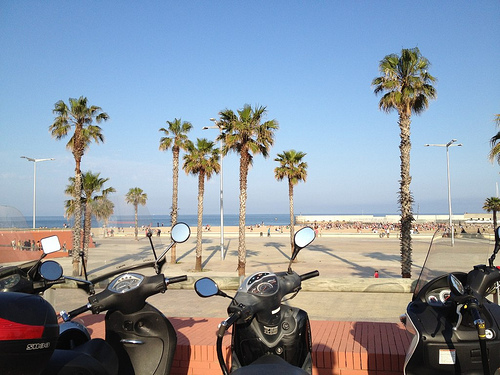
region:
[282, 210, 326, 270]
Mirror attached to handle bars.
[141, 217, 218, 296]
Mirror attached to handle bars.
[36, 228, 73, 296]
Mirrors attached to handle bars.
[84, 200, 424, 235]
Many people on the bach.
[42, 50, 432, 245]
a group of palm trees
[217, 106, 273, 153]
the fronds of a palm tree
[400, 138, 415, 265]
the trunk of a palm tree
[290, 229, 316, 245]
a side view mirror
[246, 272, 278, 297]
gauges on a scooter dash board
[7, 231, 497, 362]
a row of motorscooters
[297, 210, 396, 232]
people on a beach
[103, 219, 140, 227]
a volleyball net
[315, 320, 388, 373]
a red brick wall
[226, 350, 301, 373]
a black leather seat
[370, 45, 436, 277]
A palm tree on the beach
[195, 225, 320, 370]
A scooter parked by the beach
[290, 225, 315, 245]
The side rearview mirror of a scooter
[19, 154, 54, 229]
A street lamp on the beach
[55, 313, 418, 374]
A short brick wall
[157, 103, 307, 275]
A group of four palm trees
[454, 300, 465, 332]
The break handle of a scooter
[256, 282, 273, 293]
The speedometer of a scooter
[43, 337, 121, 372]
The seat of a scooter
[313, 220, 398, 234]
A group of beach goers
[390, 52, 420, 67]
leaves of a tree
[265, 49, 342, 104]
blue skies in the background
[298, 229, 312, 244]
side mirror of a motor bike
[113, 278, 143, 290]
the dashboard of a motor bike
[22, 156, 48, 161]
lights on a post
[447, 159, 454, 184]
a flag post in the distant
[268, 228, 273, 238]
a person walking in background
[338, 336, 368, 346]
a red brick wall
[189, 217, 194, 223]
water in the distant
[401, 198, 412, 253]
the trunk of a tree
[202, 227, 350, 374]
A black parked motorbike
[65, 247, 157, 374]
A black parked motorbike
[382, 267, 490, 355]
A black parked motorbike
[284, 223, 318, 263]
A black parked motorbike's mirror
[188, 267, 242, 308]
A black parked motorbike's mirror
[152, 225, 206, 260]
A black parked motorbike's mirror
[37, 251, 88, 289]
A black parked motorbike's mirror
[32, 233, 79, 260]
A black parked motorbike's mirror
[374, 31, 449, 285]
A tall tree with a few leaves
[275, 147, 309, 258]
A tall tree with a few leaves